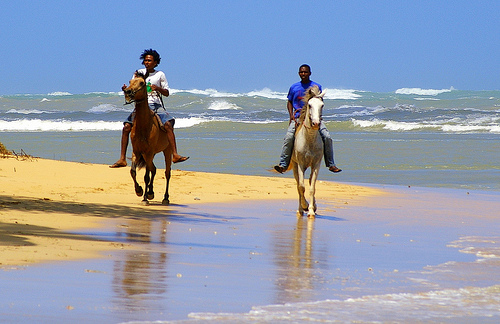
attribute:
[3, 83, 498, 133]
waves — White 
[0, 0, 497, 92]
sky — clear, bright, blue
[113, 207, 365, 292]
sand — wet, shiny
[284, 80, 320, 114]
shirt — blue 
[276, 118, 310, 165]
jeans — blue 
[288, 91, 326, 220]
horse — white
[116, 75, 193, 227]
horse — Brown 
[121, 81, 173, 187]
horse — brown, small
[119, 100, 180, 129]
shorts — jean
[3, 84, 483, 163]
ocean — turbulant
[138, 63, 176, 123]
shirt —  white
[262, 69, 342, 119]
shirt — blue